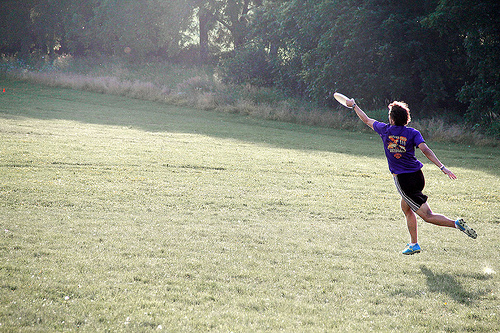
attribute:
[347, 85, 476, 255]
person — WHITE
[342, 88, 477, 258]
man — JUMPING